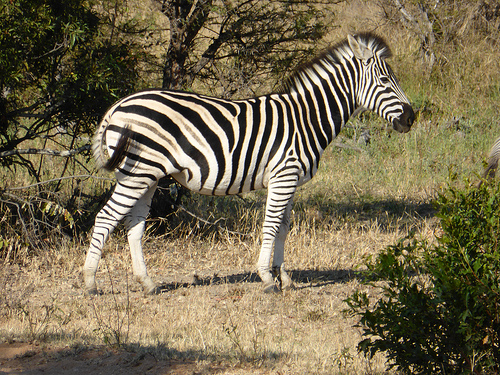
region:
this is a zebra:
[51, 30, 416, 290]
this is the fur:
[300, 65, 322, 78]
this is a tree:
[11, 4, 93, 89]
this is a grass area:
[422, 137, 444, 160]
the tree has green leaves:
[68, 24, 84, 41]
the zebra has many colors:
[202, 104, 287, 148]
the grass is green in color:
[375, 155, 383, 177]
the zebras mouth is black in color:
[395, 119, 407, 132]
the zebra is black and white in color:
[169, 106, 219, 138]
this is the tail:
[96, 124, 104, 161]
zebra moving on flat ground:
[51, 7, 442, 309]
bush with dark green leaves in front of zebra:
[345, 40, 495, 366]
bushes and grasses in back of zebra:
[5, 5, 135, 241]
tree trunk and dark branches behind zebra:
[152, 2, 312, 97]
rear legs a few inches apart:
[50, 157, 177, 309]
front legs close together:
[247, 150, 307, 305]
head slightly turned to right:
[297, 15, 437, 150]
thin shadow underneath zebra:
[156, 245, 376, 300]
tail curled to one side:
[76, 90, 163, 185]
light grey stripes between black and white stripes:
[120, 98, 212, 161]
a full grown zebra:
[66, 35, 446, 317]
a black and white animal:
[72, 26, 480, 319]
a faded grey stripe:
[119, 112, 185, 147]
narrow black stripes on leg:
[265, 172, 295, 245]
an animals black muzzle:
[388, 101, 420, 142]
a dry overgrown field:
[31, 117, 419, 363]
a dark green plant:
[329, 163, 498, 373]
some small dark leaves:
[6, 11, 48, 45]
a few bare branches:
[80, 286, 139, 353]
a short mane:
[282, 32, 389, 88]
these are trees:
[0, 0, 271, 95]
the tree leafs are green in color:
[17, 13, 127, 95]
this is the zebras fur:
[305, 68, 347, 108]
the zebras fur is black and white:
[188, 124, 275, 153]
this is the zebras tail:
[92, 115, 137, 198]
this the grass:
[375, 131, 462, 181]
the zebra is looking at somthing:
[85, 25, 418, 342]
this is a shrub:
[348, 162, 498, 368]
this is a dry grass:
[124, 291, 296, 358]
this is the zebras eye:
[368, 65, 395, 100]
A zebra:
[45, 20, 408, 318]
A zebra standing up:
[77, 22, 433, 302]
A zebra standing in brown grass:
[95, 29, 401, 317]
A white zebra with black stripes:
[61, 38, 430, 290]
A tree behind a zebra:
[142, 7, 255, 280]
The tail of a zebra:
[62, 93, 140, 205]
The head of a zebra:
[331, 21, 427, 151]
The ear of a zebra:
[333, 22, 368, 66]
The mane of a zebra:
[280, 15, 381, 76]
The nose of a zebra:
[383, 97, 421, 146]